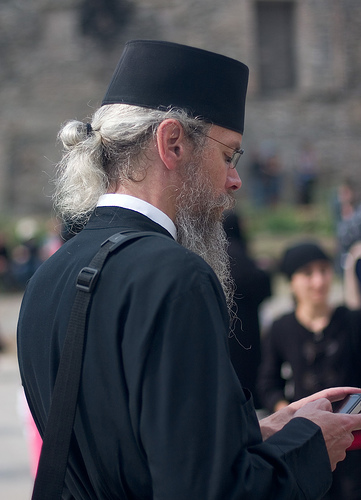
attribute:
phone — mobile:
[331, 388, 359, 414]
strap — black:
[62, 243, 178, 423]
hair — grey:
[34, 104, 170, 216]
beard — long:
[168, 195, 283, 343]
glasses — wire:
[190, 123, 242, 168]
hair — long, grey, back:
[39, 70, 156, 239]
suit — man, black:
[19, 230, 278, 495]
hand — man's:
[292, 397, 359, 470]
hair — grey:
[73, 107, 144, 183]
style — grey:
[54, 101, 140, 218]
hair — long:
[51, 103, 206, 228]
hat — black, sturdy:
[98, 38, 251, 138]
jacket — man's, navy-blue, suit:
[13, 205, 335, 498]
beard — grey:
[196, 181, 255, 344]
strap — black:
[3, 231, 140, 497]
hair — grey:
[96, 95, 180, 176]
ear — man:
[152, 116, 187, 174]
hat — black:
[76, 17, 257, 122]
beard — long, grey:
[177, 197, 238, 334]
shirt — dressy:
[128, 195, 147, 206]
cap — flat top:
[100, 52, 313, 152]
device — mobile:
[316, 384, 353, 431]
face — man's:
[191, 124, 242, 227]